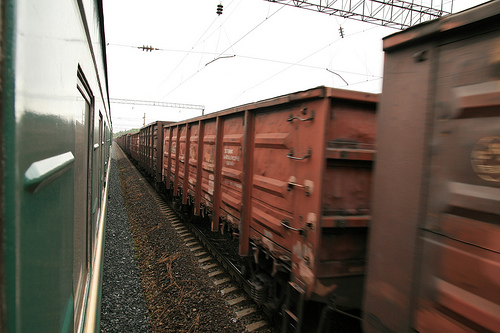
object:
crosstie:
[184, 241, 201, 245]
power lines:
[111, 0, 389, 96]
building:
[90, 84, 157, 162]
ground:
[430, 137, 475, 172]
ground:
[398, 62, 429, 94]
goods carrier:
[162, 87, 390, 288]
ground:
[197, 67, 259, 101]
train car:
[155, 84, 370, 311]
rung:
[286, 178, 313, 196]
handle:
[287, 110, 314, 121]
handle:
[286, 145, 312, 160]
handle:
[287, 181, 311, 196]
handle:
[280, 219, 305, 236]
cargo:
[160, 84, 381, 328]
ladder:
[279, 107, 314, 235]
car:
[111, 0, 498, 330]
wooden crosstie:
[220, 288, 237, 293]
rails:
[108, 141, 269, 332]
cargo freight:
[160, 84, 379, 308]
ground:
[106, 200, 211, 328]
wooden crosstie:
[169, 222, 182, 227]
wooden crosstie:
[217, 288, 238, 295]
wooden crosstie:
[246, 317, 266, 332]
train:
[0, 0, 113, 332]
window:
[77, 87, 87, 332]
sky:
[102, 0, 494, 134]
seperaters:
[223, 0, 426, 40]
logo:
[469, 129, 500, 188]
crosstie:
[196, 250, 208, 257]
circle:
[185, 146, 197, 163]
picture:
[0, 0, 500, 333]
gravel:
[98, 130, 283, 332]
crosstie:
[225, 294, 246, 305]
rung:
[286, 107, 316, 120]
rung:
[280, 217, 313, 236]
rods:
[261, 0, 445, 32]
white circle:
[107, 135, 120, 166]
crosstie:
[211, 277, 231, 285]